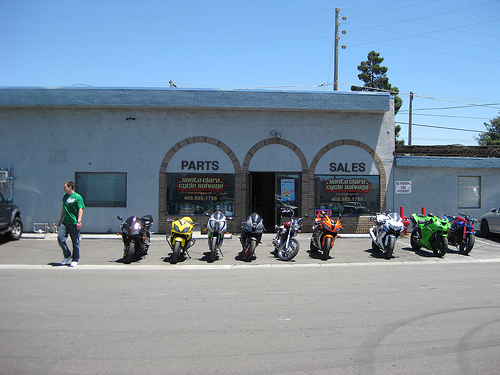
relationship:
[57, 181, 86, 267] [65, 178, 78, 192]
man has hair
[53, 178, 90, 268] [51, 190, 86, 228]
man wearing shirt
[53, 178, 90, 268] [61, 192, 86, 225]
man wearing green shirt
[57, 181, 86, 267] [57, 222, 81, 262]
man wearing jeans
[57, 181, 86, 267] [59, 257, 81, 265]
man wearing shoes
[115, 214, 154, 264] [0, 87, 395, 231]
motorcycle parked in front of store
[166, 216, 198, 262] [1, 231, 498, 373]
bike parked in front of store`s front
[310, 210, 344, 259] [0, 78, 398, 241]
bike parked in front of store front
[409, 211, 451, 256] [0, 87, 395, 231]
bike parked in front of store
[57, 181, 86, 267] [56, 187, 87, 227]
man wearing t-shirt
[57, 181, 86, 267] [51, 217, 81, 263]
man wearing jeans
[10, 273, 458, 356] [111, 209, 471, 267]
road in front of motorcycles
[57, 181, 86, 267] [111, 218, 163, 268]
man walking away from motorcycle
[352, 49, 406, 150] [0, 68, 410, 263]
tree behind building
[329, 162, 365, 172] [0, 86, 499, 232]
sales on building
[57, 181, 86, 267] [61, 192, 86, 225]
man wearing green shirt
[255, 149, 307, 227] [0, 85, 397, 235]
door to building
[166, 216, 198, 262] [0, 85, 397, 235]
bike outside building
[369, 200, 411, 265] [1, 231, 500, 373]
motorcycle parked on store`s front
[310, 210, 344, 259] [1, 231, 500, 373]
bike parked on store`s front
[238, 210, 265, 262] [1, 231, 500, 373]
motorcycle parked on store`s front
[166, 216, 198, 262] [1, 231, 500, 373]
bike parked on store`s front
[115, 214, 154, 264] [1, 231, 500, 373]
motorcycle parked on store`s front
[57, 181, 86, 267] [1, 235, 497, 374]
man standing on street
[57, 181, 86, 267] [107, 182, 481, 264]
man standing next to motorcycles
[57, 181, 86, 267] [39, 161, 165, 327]
man wearing green shirt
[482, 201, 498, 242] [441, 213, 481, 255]
automobile parked next to motorcycle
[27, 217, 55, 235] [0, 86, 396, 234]
pipe sticking out of building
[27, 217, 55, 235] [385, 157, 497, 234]
pipe sticking out of building wall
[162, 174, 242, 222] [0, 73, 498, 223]
front window on motorcycle shop